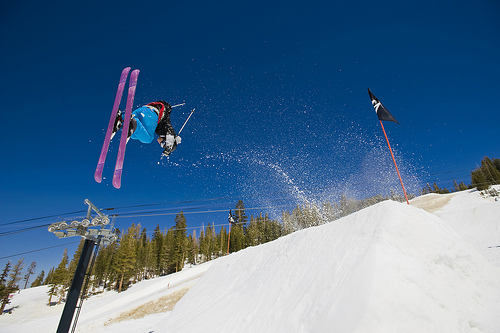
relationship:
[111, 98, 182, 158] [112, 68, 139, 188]
person jumping ski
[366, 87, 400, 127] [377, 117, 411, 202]
flag on pole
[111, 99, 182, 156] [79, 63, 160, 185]
person wearing skis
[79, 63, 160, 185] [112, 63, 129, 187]
skis wearing ski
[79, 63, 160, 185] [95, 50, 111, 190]
skis wearing ski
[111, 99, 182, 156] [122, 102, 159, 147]
person wearing pants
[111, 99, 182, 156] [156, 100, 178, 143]
person wearing black jacket